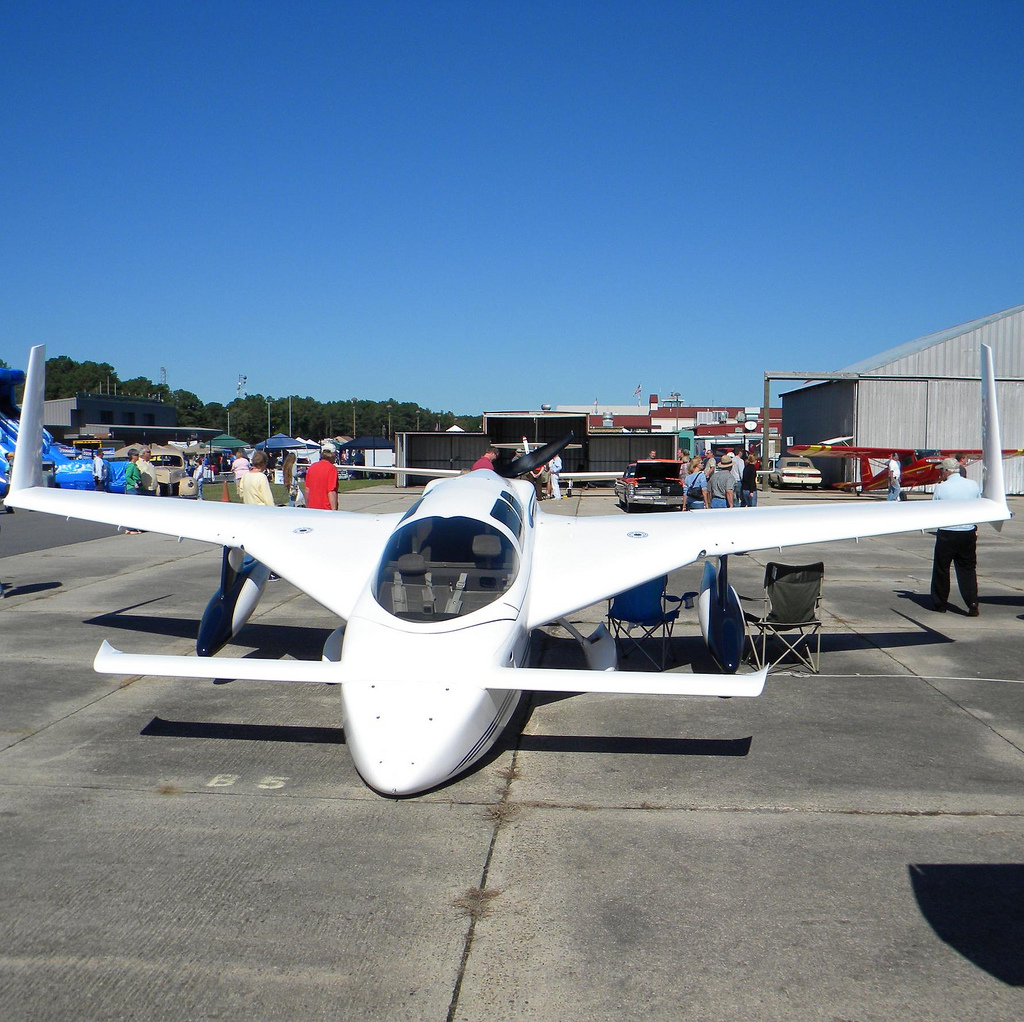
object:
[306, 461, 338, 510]
shirt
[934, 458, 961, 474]
hat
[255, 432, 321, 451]
blue tent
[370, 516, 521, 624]
window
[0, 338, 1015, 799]
plane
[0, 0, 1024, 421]
sky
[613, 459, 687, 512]
car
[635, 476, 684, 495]
bonnet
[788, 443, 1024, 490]
aircraft